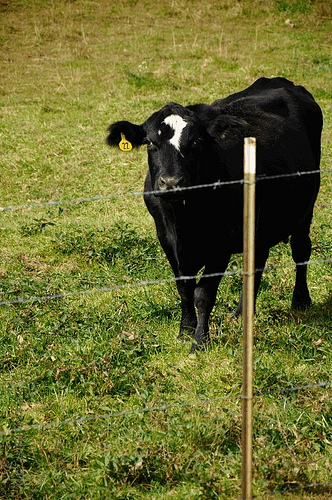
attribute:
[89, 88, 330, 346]
cow — black, yellow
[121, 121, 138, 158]
tag — yellow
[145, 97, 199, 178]
head — white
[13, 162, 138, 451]
fence — wire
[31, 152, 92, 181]
field — green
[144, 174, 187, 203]
nose — black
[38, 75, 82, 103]
grass — green, short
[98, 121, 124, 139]
ear — black